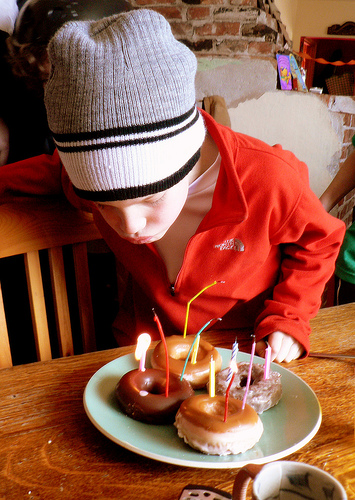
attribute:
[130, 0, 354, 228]
wall — brick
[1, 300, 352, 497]
table — brown, wooden